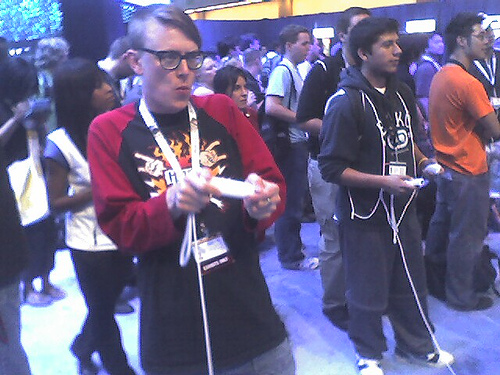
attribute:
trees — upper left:
[0, 4, 60, 35]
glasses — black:
[133, 48, 205, 69]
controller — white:
[207, 174, 256, 199]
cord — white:
[191, 216, 215, 374]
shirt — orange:
[427, 60, 494, 173]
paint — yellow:
[208, 3, 301, 22]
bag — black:
[258, 120, 288, 153]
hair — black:
[50, 63, 97, 117]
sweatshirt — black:
[322, 88, 425, 177]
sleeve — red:
[81, 110, 175, 249]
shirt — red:
[87, 86, 295, 361]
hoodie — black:
[319, 68, 435, 192]